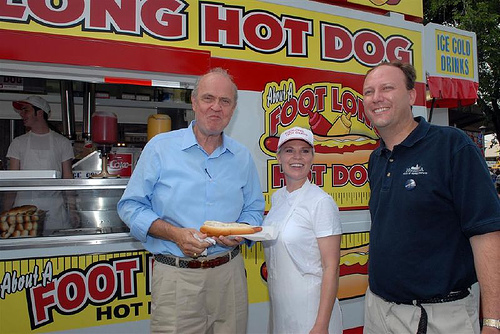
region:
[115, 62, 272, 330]
A person is standing up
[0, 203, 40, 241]
stack of hot dog buns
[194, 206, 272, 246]
hot dog in a bun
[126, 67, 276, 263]
man holding a hot dog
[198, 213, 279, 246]
hot dog on the paper wrapper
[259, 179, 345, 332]
woman is wearing an apron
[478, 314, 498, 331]
man is wearing a watch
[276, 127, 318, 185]
woman is wearing a ball cap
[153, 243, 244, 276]
man is wearing a belt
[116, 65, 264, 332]
a man holding a hot dog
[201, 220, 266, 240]
a freshly served hot dog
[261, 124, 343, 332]
a female food service employee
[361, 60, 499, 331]
a man standing near the hot dog truck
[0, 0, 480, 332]
a brightly-colored hot dog truck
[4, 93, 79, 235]
a hot dog truck employee inside of the truck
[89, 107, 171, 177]
large containers of ketchup and mustard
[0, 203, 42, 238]
a stack of hot dog buns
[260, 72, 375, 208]
the logo of the hot dog truck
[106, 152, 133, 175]
a Coke advertisement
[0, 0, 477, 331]
people standing in front of a hot dog stand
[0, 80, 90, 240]
person behind counter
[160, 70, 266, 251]
man holding a hot dog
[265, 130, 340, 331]
woman wearing a white apron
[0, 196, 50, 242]
stacked hot dog buns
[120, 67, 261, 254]
man wearing a pale blue dress shirt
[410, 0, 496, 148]
tree to the right of stand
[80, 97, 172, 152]
large red and yellow containers within stand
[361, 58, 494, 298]
man wearing a dark blue polo shirt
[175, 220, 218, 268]
man holding napkin in his right hand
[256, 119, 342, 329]
an employee wearing a white uniform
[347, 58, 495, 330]
a man wearing a dark blue shirt and khakis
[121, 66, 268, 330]
a man wearing a blue shirt and khakis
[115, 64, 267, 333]
a man eating a hot dog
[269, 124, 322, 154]
a white hat with red lettering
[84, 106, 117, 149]
a commercial bottle of ketchup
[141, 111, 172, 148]
a commercial bottle of mustard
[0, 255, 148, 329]
painted words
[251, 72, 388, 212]
a painted business logo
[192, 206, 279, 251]
man holding a hot dog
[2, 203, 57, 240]
a pack of hot dog buns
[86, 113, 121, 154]
container of ketchup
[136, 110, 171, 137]
a contaner of mustard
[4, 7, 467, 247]
a hot dog truck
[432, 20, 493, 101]
ice cold drinks sign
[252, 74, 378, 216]
foot long hot dog sign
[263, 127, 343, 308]
lady in a white uniform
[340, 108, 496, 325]
blue short sleeveshirt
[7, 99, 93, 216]
male in white unifrm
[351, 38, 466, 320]
man with short dark hair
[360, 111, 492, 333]
man wearing short sleeve pullover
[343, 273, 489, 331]
man wearing black leather belt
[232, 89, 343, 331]
woman wearing a white cape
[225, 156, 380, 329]
woman wearing white uniform with apron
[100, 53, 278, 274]
man eating a foot long hotdog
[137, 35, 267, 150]
man with short blond hair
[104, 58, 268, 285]
man wearing long sleeve dress blue shirt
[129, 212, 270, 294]
man wearing brown leather belt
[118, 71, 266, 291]
man with ink pen stuck in his shirt